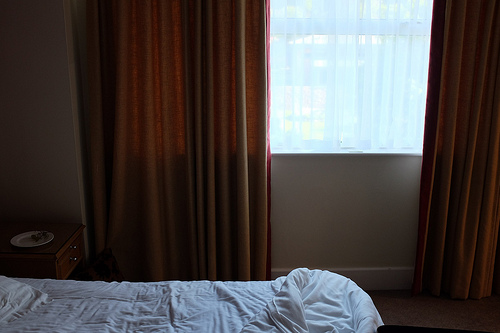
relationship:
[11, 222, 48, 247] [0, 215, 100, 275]
plate on stand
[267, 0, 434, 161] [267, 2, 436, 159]
white shears are on window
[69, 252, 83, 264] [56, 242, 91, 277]
knob on a drawer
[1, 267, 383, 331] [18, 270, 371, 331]
bed has sheets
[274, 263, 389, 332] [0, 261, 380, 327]
pillow on bed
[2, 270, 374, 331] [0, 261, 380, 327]
blanket on bed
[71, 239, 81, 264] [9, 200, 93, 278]
knobs on stand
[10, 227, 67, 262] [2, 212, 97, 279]
plate on top of night stand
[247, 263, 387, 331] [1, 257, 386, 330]
sheet on bed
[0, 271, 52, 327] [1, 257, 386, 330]
pillow on bed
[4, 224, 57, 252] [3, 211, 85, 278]
plate on nightstand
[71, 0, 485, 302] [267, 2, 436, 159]
curtains hanging in window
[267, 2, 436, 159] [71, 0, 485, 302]
window has curtains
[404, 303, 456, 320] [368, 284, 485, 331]
carpet on floor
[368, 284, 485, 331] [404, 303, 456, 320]
floor has carpet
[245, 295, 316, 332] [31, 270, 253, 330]
sheet at end of bed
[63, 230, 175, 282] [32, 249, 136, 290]
drawer has handles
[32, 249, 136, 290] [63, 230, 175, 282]
handles on drawer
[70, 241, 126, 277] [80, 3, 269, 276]
pillow laying against curtain